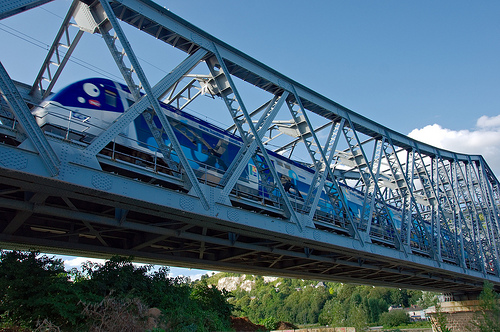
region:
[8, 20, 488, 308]
The train is going over a bridge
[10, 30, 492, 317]
The train is traveling very fast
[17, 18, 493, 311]
The train is carrying passengers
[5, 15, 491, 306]
The train is going to the city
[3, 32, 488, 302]
The train is pulling many cars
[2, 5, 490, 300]
The train is bringing people to work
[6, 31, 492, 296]
The train has vacationers on board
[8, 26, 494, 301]
The train is traveling in daytime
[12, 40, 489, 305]
The train is running late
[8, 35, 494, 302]
The train is right on schedule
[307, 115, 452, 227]
an overpass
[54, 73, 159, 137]
a train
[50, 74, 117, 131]
a blue and grey train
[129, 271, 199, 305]
the green bushes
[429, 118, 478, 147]
clouds in the sky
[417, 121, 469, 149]
the clouds are white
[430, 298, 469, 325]
a brick wall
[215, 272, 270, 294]
rocks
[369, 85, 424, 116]
the blue sky is clear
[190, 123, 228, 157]
windows on the train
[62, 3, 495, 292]
train going over bridge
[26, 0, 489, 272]
train traveling on bridge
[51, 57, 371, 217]
blue and white train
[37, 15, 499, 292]
blue and white train on bridge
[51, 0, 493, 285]
train on bridge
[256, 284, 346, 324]
green tree leaves in back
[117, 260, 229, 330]
green tree leaves in back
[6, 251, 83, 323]
green tree leaves in back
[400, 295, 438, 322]
house in the distance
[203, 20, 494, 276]
metal structure of bridge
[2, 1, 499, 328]
train crossing river on bridge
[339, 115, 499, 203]
fluffy white cloud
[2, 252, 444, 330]
trees on river bank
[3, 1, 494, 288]
metal train bridge with crossing train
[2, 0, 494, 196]
blue sky with white clouds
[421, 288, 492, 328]
bridge support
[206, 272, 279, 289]
steep rocky bluff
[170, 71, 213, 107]
train bridge horizontal brace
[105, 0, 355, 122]
metal train bridge beam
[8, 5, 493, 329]
modern train crossing a bridge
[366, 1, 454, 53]
this is the sky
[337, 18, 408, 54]
the sky is blue in color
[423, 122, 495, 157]
this is the clouds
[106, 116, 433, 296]
this is the bridge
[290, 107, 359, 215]
this is a metal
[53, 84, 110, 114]
this is a train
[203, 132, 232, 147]
the train is blue in color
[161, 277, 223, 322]
this is a tree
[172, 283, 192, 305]
the leaves are green in color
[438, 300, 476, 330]
this is a wall